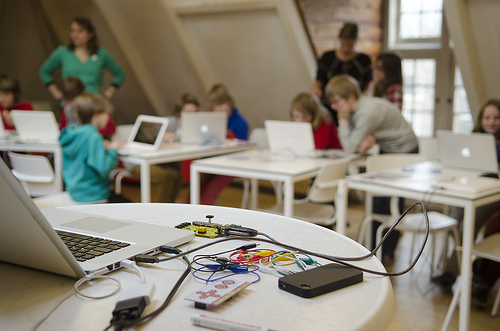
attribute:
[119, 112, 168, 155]
laptop — white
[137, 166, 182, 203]
pants — brown 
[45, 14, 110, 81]
girl — young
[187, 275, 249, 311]
controller — red, white 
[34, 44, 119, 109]
shirt — long sleeve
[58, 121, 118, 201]
shirt — blue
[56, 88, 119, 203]
boy — young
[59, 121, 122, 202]
sweatshirt — blue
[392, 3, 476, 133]
paned windows — multi paned 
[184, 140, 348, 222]
table — square , white 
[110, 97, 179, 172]
computer — large , white , laptop 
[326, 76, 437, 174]
boy — young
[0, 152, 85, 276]
cover — open  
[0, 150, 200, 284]
laptop — Silver 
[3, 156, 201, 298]
laptop — silver 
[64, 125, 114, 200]
shirt — green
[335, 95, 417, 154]
sweater — grey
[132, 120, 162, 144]
screen — black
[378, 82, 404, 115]
shirt — plaid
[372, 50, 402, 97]
hair — brown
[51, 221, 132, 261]
buttons — black  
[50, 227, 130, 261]
keyboard — black 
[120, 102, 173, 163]
laptop — white 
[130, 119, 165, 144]
monitor face — black 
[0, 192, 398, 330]
table — white 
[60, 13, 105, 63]
hair — dark 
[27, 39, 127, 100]
shirt — green 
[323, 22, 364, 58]
hair — dark 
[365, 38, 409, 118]
student — female 